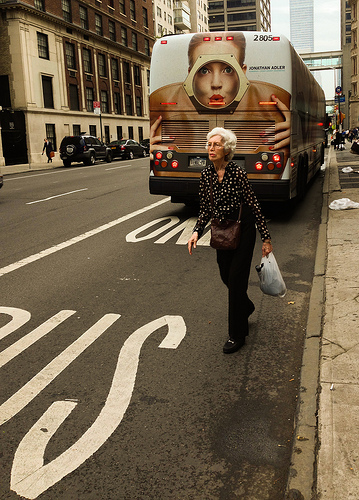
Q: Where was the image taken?
A: It was taken at the road.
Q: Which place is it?
A: It is a road.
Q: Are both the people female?
A: No, they are both male and female.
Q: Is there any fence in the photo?
A: No, there are no fences.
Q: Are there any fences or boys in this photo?
A: No, there are no fences or boys.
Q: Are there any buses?
A: Yes, there is a bus.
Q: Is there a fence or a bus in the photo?
A: Yes, there is a bus.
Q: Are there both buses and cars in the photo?
A: Yes, there are both a bus and a car.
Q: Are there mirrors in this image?
A: No, there are no mirrors.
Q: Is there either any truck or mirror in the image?
A: No, there are no mirrors or trucks.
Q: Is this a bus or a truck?
A: This is a bus.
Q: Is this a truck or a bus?
A: This is a bus.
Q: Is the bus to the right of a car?
A: Yes, the bus is to the right of a car.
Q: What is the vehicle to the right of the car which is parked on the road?
A: The vehicle is a bus.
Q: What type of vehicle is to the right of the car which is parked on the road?
A: The vehicle is a bus.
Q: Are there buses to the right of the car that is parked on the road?
A: Yes, there is a bus to the right of the car.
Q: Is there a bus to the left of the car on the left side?
A: No, the bus is to the right of the car.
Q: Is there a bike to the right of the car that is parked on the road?
A: No, there is a bus to the right of the car.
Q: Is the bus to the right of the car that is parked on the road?
A: Yes, the bus is to the right of the car.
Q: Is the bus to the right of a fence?
A: No, the bus is to the right of the car.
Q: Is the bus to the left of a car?
A: No, the bus is to the right of a car.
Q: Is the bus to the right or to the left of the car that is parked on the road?
A: The bus is to the right of the car.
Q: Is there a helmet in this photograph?
A: No, there are no helmets.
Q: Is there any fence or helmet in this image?
A: No, there are no helmets or fences.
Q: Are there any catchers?
A: No, there are no catchers.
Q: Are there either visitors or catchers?
A: No, there are no catchers or visitors.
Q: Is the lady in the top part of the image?
A: Yes, the lady is in the top of the image.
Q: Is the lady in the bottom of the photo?
A: No, the lady is in the top of the image.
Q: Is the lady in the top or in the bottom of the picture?
A: The lady is in the top of the image.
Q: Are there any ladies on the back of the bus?
A: Yes, there is a lady on the back of the bus.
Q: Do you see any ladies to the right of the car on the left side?
A: Yes, there is a lady to the right of the car.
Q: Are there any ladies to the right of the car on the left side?
A: Yes, there is a lady to the right of the car.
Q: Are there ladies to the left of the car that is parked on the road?
A: No, the lady is to the right of the car.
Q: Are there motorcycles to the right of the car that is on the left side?
A: No, there is a lady to the right of the car.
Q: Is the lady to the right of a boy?
A: No, the lady is to the right of a car.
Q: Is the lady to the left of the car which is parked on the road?
A: No, the lady is to the right of the car.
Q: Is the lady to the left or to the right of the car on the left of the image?
A: The lady is to the right of the car.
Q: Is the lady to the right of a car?
A: Yes, the lady is to the right of a car.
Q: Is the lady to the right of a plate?
A: No, the lady is to the right of a car.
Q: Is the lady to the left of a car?
A: No, the lady is to the right of a car.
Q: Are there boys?
A: No, there are no boys.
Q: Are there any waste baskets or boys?
A: No, there are no boys or waste baskets.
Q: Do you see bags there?
A: Yes, there is a bag.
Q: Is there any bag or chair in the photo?
A: Yes, there is a bag.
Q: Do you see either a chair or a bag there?
A: Yes, there is a bag.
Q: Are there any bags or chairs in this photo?
A: Yes, there is a bag.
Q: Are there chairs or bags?
A: Yes, there is a bag.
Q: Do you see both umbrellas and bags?
A: No, there is a bag but no umbrellas.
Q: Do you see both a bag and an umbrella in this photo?
A: No, there is a bag but no umbrellas.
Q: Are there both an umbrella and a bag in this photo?
A: No, there is a bag but no umbrellas.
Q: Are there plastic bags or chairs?
A: Yes, there is a plastic bag.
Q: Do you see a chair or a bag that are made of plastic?
A: Yes, the bag is made of plastic.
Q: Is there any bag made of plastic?
A: Yes, there is a bag that is made of plastic.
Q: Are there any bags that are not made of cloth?
A: Yes, there is a bag that is made of plastic.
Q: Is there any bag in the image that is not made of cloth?
A: Yes, there is a bag that is made of plastic.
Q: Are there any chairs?
A: No, there are no chairs.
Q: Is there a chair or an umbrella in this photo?
A: No, there are no chairs or umbrellas.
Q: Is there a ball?
A: No, there are no balls.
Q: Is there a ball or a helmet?
A: No, there are no balls or helmets.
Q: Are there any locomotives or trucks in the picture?
A: No, there are no trucks or locomotives.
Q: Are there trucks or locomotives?
A: No, there are no trucks or locomotives.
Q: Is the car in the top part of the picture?
A: Yes, the car is in the top of the image.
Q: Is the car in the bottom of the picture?
A: No, the car is in the top of the image.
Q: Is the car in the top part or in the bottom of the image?
A: The car is in the top of the image.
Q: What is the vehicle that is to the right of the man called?
A: The vehicle is a car.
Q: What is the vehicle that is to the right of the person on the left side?
A: The vehicle is a car.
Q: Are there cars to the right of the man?
A: Yes, there is a car to the right of the man.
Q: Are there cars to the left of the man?
A: No, the car is to the right of the man.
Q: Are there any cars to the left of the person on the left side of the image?
A: No, the car is to the right of the man.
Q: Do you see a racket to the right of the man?
A: No, there is a car to the right of the man.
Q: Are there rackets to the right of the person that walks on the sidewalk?
A: No, there is a car to the right of the man.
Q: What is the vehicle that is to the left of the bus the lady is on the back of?
A: The vehicle is a car.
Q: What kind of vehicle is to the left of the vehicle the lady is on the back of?
A: The vehicle is a car.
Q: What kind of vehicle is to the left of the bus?
A: The vehicle is a car.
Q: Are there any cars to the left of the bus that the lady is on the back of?
A: Yes, there is a car to the left of the bus.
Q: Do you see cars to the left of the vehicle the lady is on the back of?
A: Yes, there is a car to the left of the bus.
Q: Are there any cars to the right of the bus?
A: No, the car is to the left of the bus.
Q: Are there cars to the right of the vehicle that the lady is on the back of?
A: No, the car is to the left of the bus.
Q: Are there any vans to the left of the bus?
A: No, there is a car to the left of the bus.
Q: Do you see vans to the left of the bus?
A: No, there is a car to the left of the bus.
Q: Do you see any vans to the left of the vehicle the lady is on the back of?
A: No, there is a car to the left of the bus.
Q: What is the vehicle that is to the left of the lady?
A: The vehicle is a car.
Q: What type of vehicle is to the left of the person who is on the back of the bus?
A: The vehicle is a car.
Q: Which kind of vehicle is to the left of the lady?
A: The vehicle is a car.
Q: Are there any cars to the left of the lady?
A: Yes, there is a car to the left of the lady.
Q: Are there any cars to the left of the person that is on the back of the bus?
A: Yes, there is a car to the left of the lady.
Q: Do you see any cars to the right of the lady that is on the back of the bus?
A: No, the car is to the left of the lady.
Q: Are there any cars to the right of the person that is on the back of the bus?
A: No, the car is to the left of the lady.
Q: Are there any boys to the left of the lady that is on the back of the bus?
A: No, there is a car to the left of the lady.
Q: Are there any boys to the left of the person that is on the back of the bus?
A: No, there is a car to the left of the lady.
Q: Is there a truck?
A: No, there are no trucks.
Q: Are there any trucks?
A: No, there are no trucks.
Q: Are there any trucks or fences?
A: No, there are no trucks or fences.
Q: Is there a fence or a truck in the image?
A: No, there are no trucks or fences.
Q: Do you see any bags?
A: Yes, there is a bag.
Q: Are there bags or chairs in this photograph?
A: Yes, there is a bag.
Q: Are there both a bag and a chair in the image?
A: No, there is a bag but no chairs.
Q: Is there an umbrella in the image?
A: No, there are no umbrellas.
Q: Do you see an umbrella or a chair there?
A: No, there are no umbrellas or chairs.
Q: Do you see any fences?
A: No, there are no fences.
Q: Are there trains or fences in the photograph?
A: No, there are no fences or trains.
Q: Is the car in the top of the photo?
A: Yes, the car is in the top of the image.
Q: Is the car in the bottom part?
A: No, the car is in the top of the image.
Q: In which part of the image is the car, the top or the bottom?
A: The car is in the top of the image.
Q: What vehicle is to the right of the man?
A: The vehicle is a car.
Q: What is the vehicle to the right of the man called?
A: The vehicle is a car.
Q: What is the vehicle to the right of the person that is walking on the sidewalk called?
A: The vehicle is a car.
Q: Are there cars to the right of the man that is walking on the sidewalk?
A: Yes, there is a car to the right of the man.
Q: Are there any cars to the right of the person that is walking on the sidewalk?
A: Yes, there is a car to the right of the man.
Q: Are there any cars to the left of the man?
A: No, the car is to the right of the man.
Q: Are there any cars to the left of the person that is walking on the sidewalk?
A: No, the car is to the right of the man.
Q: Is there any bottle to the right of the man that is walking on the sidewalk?
A: No, there is a car to the right of the man.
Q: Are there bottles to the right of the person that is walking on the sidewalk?
A: No, there is a car to the right of the man.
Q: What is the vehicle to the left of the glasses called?
A: The vehicle is a car.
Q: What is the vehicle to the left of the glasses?
A: The vehicle is a car.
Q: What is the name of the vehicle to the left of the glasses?
A: The vehicle is a car.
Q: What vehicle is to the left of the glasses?
A: The vehicle is a car.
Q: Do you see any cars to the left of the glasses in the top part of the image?
A: Yes, there is a car to the left of the glasses.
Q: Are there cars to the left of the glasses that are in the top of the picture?
A: Yes, there is a car to the left of the glasses.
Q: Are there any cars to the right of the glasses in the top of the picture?
A: No, the car is to the left of the glasses.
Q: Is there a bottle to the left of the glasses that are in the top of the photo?
A: No, there is a car to the left of the glasses.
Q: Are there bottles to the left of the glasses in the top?
A: No, there is a car to the left of the glasses.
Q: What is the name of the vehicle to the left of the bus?
A: The vehicle is a car.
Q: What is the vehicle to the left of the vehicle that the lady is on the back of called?
A: The vehicle is a car.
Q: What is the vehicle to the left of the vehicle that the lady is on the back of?
A: The vehicle is a car.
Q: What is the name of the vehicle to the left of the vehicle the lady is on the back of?
A: The vehicle is a car.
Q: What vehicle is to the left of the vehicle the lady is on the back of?
A: The vehicle is a car.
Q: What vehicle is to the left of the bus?
A: The vehicle is a car.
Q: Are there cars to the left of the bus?
A: Yes, there is a car to the left of the bus.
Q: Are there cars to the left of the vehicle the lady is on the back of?
A: Yes, there is a car to the left of the bus.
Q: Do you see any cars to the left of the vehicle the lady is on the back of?
A: Yes, there is a car to the left of the bus.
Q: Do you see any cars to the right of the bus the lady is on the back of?
A: No, the car is to the left of the bus.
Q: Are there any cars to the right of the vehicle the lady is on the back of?
A: No, the car is to the left of the bus.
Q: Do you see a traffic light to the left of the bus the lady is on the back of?
A: No, there is a car to the left of the bus.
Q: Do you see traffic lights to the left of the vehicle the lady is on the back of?
A: No, there is a car to the left of the bus.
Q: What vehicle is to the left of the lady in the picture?
A: The vehicle is a car.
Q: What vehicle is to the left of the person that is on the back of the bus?
A: The vehicle is a car.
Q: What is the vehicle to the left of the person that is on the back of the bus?
A: The vehicle is a car.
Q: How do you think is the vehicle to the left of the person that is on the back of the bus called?
A: The vehicle is a car.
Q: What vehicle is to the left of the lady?
A: The vehicle is a car.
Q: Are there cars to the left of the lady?
A: Yes, there is a car to the left of the lady.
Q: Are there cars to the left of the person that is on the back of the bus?
A: Yes, there is a car to the left of the lady.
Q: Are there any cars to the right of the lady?
A: No, the car is to the left of the lady.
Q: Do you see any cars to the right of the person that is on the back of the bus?
A: No, the car is to the left of the lady.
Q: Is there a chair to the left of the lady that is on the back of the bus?
A: No, there is a car to the left of the lady.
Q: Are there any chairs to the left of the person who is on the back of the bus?
A: No, there is a car to the left of the lady.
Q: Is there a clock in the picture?
A: No, there are no clocks.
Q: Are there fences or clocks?
A: No, there are no clocks or fences.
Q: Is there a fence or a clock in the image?
A: No, there are no clocks or fences.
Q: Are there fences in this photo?
A: No, there are no fences.